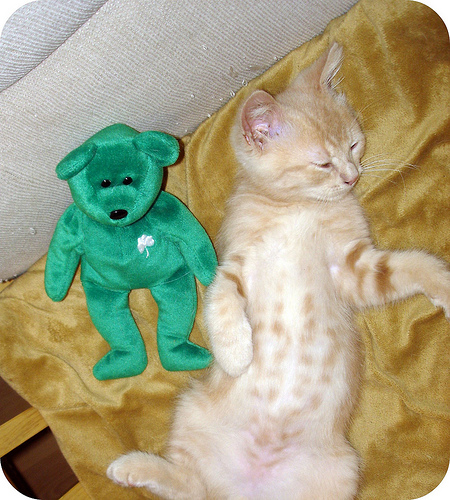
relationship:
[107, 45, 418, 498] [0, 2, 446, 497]
kitten laying on couch